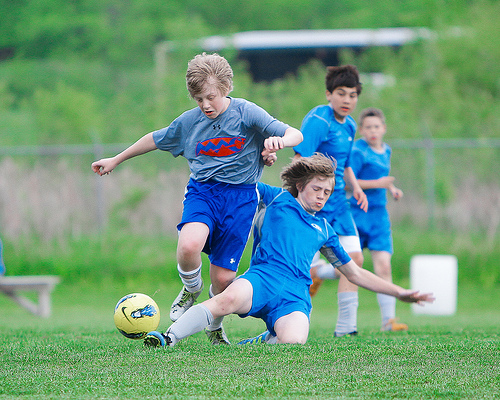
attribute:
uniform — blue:
[234, 175, 349, 335]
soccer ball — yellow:
[111, 292, 161, 339]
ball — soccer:
[101, 282, 173, 339]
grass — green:
[2, 290, 497, 396]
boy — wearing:
[88, 47, 309, 329]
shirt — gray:
[251, 187, 351, 286]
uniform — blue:
[159, 105, 261, 183]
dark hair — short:
[326, 67, 348, 85]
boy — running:
[88, 41, 300, 347]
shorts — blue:
[230, 260, 315, 327]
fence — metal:
[2, 136, 499, 262]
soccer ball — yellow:
[110, 292, 186, 352]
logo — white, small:
[228, 253, 240, 265]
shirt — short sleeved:
[150, 112, 287, 202]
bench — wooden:
[1, 275, 60, 316]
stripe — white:
[249, 187, 261, 207]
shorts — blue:
[172, 174, 259, 278]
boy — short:
[107, 40, 289, 315]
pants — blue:
[171, 166, 282, 277]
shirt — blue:
[154, 95, 288, 185]